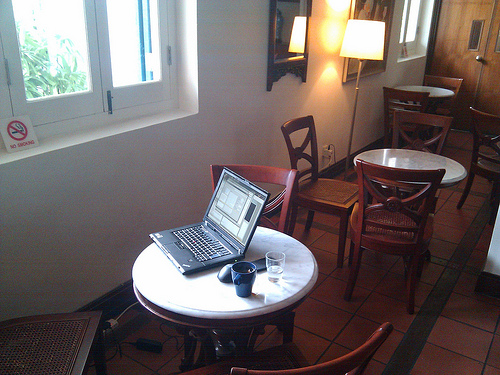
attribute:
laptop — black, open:
[148, 166, 270, 276]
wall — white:
[4, 0, 434, 320]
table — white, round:
[131, 226, 318, 371]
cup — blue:
[231, 261, 255, 297]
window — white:
[0, 0, 178, 140]